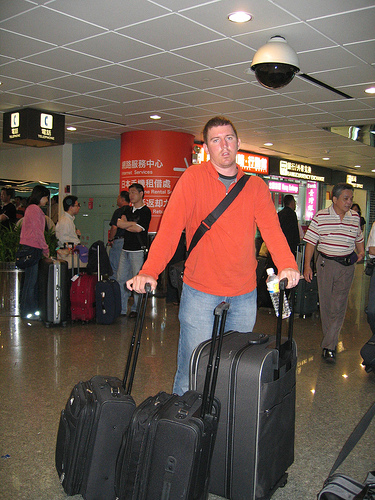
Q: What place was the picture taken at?
A: It was taken at the airport.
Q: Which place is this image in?
A: It is at the airport.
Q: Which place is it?
A: It is an airport.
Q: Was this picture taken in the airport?
A: Yes, it was taken in the airport.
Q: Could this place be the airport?
A: Yes, it is the airport.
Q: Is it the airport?
A: Yes, it is the airport.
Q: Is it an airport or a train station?
A: It is an airport.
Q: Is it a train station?
A: No, it is an airport.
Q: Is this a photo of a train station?
A: No, the picture is showing an airport.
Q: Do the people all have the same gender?
A: No, they are both male and female.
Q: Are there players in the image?
A: No, there are no players.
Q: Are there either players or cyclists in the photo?
A: No, there are no players or cyclists.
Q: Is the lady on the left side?
A: Yes, the lady is on the left of the image.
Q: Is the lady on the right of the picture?
A: No, the lady is on the left of the image.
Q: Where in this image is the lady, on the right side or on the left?
A: The lady is on the left of the image.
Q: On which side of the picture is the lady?
A: The lady is on the left of the image.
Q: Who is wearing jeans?
A: The lady is wearing jeans.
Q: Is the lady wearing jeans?
A: Yes, the lady is wearing jeans.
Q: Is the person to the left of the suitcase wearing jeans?
A: Yes, the lady is wearing jeans.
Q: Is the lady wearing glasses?
A: No, the lady is wearing jeans.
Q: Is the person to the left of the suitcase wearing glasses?
A: No, the lady is wearing jeans.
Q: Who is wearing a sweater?
A: The lady is wearing a sweater.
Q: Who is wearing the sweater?
A: The lady is wearing a sweater.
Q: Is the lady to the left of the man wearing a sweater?
A: Yes, the lady is wearing a sweater.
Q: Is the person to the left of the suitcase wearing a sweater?
A: Yes, the lady is wearing a sweater.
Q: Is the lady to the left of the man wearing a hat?
A: No, the lady is wearing a sweater.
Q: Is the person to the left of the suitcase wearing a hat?
A: No, the lady is wearing a sweater.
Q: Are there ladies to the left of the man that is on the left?
A: Yes, there is a lady to the left of the man.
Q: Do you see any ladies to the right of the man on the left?
A: No, the lady is to the left of the man.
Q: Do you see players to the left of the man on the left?
A: No, there is a lady to the left of the man.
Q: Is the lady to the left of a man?
A: Yes, the lady is to the left of a man.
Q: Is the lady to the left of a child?
A: No, the lady is to the left of a man.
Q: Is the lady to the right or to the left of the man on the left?
A: The lady is to the left of the man.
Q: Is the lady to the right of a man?
A: No, the lady is to the left of a man.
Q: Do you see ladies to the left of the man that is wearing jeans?
A: Yes, there is a lady to the left of the man.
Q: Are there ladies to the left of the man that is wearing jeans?
A: Yes, there is a lady to the left of the man.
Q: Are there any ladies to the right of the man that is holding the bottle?
A: No, the lady is to the left of the man.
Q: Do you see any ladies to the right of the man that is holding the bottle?
A: No, the lady is to the left of the man.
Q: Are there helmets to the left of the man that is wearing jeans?
A: No, there is a lady to the left of the man.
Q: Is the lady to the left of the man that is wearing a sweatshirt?
A: Yes, the lady is to the left of the man.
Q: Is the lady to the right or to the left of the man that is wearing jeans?
A: The lady is to the left of the man.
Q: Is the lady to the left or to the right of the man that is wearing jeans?
A: The lady is to the left of the man.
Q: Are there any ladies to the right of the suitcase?
A: No, the lady is to the left of the suitcase.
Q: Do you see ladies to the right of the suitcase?
A: No, the lady is to the left of the suitcase.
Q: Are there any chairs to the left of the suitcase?
A: No, there is a lady to the left of the suitcase.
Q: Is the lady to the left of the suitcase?
A: Yes, the lady is to the left of the suitcase.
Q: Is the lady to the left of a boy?
A: No, the lady is to the left of the suitcase.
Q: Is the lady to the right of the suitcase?
A: No, the lady is to the left of the suitcase.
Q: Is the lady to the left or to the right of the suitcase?
A: The lady is to the left of the suitcase.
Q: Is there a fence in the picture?
A: No, there are no fences.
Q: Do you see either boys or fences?
A: No, there are no fences or boys.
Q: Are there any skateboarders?
A: No, there are no skateboarders.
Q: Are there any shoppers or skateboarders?
A: No, there are no skateboarders or shoppers.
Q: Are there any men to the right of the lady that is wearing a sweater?
A: Yes, there is a man to the right of the lady.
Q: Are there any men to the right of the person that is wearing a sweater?
A: Yes, there is a man to the right of the lady.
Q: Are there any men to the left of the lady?
A: No, the man is to the right of the lady.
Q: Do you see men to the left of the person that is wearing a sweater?
A: No, the man is to the right of the lady.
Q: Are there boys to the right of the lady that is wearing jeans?
A: No, there is a man to the right of the lady.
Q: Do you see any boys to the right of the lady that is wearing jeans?
A: No, there is a man to the right of the lady.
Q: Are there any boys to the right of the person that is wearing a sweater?
A: No, there is a man to the right of the lady.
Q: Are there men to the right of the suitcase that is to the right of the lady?
A: Yes, there is a man to the right of the suitcase.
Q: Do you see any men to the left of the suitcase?
A: No, the man is to the right of the suitcase.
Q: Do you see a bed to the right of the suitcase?
A: No, there is a man to the right of the suitcase.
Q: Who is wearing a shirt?
A: The man is wearing a shirt.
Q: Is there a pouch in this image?
A: Yes, there is a pouch.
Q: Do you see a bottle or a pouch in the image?
A: Yes, there is a pouch.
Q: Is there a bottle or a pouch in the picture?
A: Yes, there is a pouch.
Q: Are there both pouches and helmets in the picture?
A: No, there is a pouch but no helmets.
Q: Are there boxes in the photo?
A: No, there are no boxes.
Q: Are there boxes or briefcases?
A: No, there are no boxes or briefcases.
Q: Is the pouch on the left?
A: No, the pouch is on the right of the image.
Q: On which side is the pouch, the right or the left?
A: The pouch is on the right of the image.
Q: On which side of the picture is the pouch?
A: The pouch is on the right of the image.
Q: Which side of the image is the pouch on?
A: The pouch is on the right of the image.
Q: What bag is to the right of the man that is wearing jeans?
A: The bag is a pouch.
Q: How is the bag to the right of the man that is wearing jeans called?
A: The bag is a pouch.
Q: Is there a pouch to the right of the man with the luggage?
A: Yes, there is a pouch to the right of the man.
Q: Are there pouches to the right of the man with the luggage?
A: Yes, there is a pouch to the right of the man.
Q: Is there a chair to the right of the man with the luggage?
A: No, there is a pouch to the right of the man.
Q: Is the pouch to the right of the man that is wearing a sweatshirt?
A: Yes, the pouch is to the right of the man.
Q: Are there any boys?
A: No, there are no boys.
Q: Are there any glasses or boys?
A: No, there are no boys or glasses.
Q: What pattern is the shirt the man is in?
A: The shirt is striped.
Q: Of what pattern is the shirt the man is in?
A: The shirt is striped.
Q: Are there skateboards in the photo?
A: No, there are no skateboards.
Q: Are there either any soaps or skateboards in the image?
A: No, there are no skateboards or soaps.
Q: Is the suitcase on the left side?
A: Yes, the suitcase is on the left of the image.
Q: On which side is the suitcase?
A: The suitcase is on the left of the image.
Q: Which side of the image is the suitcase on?
A: The suitcase is on the left of the image.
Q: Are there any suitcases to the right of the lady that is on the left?
A: Yes, there is a suitcase to the right of the lady.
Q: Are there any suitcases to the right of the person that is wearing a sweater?
A: Yes, there is a suitcase to the right of the lady.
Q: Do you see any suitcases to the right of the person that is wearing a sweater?
A: Yes, there is a suitcase to the right of the lady.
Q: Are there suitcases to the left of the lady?
A: No, the suitcase is to the right of the lady.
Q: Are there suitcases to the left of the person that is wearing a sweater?
A: No, the suitcase is to the right of the lady.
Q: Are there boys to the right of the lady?
A: No, there is a suitcase to the right of the lady.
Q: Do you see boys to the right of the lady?
A: No, there is a suitcase to the right of the lady.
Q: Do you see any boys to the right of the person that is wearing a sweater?
A: No, there is a suitcase to the right of the lady.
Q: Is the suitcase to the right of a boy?
A: No, the suitcase is to the right of the lady.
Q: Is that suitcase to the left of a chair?
A: No, the suitcase is to the left of a man.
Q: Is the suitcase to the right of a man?
A: No, the suitcase is to the left of a man.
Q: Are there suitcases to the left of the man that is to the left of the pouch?
A: Yes, there is a suitcase to the left of the man.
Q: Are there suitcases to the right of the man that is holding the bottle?
A: No, the suitcase is to the left of the man.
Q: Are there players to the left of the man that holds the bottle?
A: No, there is a suitcase to the left of the man.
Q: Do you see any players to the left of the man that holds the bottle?
A: No, there is a suitcase to the left of the man.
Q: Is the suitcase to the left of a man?
A: Yes, the suitcase is to the left of a man.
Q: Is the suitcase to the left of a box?
A: No, the suitcase is to the left of a man.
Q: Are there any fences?
A: No, there are no fences.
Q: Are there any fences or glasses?
A: No, there are no fences or glasses.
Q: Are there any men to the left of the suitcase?
A: No, the man is to the right of the suitcase.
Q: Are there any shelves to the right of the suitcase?
A: No, there is a man to the right of the suitcase.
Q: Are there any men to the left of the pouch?
A: Yes, there is a man to the left of the pouch.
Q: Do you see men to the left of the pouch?
A: Yes, there is a man to the left of the pouch.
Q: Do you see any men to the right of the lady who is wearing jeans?
A: Yes, there is a man to the right of the lady.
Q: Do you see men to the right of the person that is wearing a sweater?
A: Yes, there is a man to the right of the lady.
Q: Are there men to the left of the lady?
A: No, the man is to the right of the lady.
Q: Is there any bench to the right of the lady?
A: No, there is a man to the right of the lady.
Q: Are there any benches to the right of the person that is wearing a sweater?
A: No, there is a man to the right of the lady.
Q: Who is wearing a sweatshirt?
A: The man is wearing a sweatshirt.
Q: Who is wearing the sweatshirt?
A: The man is wearing a sweatshirt.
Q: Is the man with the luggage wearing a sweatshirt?
A: Yes, the man is wearing a sweatshirt.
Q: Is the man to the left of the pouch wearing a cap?
A: No, the man is wearing a sweatshirt.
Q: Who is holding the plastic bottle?
A: The man is holding the bottle.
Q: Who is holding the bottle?
A: The man is holding the bottle.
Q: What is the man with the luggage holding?
A: The man is holding the bottle.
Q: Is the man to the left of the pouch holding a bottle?
A: Yes, the man is holding a bottle.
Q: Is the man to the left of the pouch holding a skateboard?
A: No, the man is holding a bottle.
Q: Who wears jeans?
A: The man wears jeans.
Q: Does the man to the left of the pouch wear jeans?
A: Yes, the man wears jeans.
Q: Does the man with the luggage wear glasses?
A: No, the man wears jeans.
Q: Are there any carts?
A: No, there are no carts.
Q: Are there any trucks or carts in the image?
A: No, there are no carts or trucks.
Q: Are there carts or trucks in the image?
A: No, there are no carts or trucks.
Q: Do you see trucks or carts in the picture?
A: No, there are no carts or trucks.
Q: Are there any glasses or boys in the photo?
A: No, there are no glasses or boys.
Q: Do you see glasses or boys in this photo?
A: No, there are no glasses or boys.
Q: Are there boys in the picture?
A: No, there are no boys.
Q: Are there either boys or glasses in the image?
A: No, there are no boys or glasses.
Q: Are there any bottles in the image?
A: Yes, there is a bottle.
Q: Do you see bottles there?
A: Yes, there is a bottle.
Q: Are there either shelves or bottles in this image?
A: Yes, there is a bottle.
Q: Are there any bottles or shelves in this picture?
A: Yes, there is a bottle.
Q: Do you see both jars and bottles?
A: No, there is a bottle but no jars.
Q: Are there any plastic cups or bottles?
A: Yes, there is a plastic bottle.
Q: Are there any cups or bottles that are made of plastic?
A: Yes, the bottle is made of plastic.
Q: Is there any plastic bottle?
A: Yes, there is a bottle that is made of plastic.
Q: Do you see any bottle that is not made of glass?
A: Yes, there is a bottle that is made of plastic.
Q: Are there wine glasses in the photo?
A: No, there are no wine glasses.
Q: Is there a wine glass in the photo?
A: No, there are no wine glasses.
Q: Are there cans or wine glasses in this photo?
A: No, there are no wine glasses or cans.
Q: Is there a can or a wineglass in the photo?
A: No, there are no wine glasses or cans.